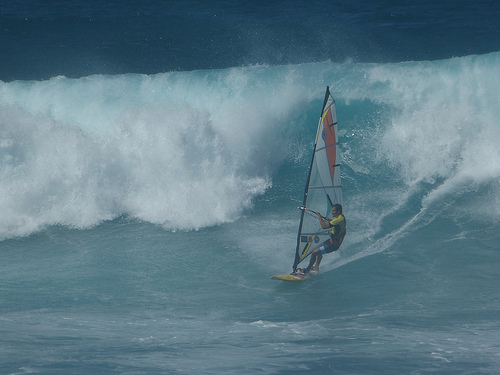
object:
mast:
[293, 92, 343, 276]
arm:
[315, 217, 337, 229]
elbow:
[321, 224, 328, 229]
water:
[0, 52, 497, 375]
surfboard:
[269, 263, 315, 281]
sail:
[291, 84, 344, 268]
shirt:
[328, 218, 349, 241]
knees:
[310, 247, 317, 256]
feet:
[291, 268, 306, 275]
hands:
[317, 216, 324, 221]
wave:
[340, 54, 500, 215]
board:
[266, 264, 318, 281]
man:
[288, 204, 345, 274]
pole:
[293, 88, 349, 272]